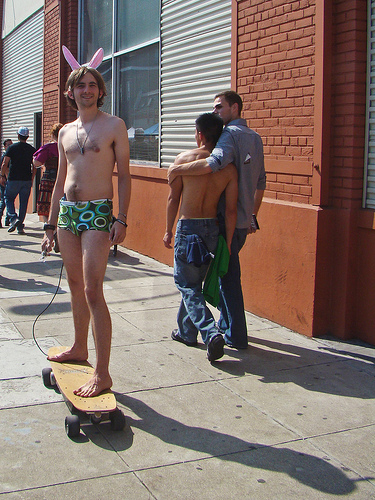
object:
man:
[40, 45, 132, 398]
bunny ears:
[62, 44, 105, 71]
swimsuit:
[57, 196, 114, 237]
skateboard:
[41, 346, 127, 439]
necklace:
[75, 109, 99, 157]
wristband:
[116, 212, 129, 226]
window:
[77, 2, 160, 168]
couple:
[163, 90, 266, 361]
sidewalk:
[0, 206, 375, 500]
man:
[162, 113, 239, 362]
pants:
[172, 218, 225, 363]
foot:
[46, 348, 113, 399]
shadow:
[111, 391, 357, 497]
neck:
[78, 101, 99, 120]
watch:
[42, 222, 56, 232]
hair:
[62, 67, 109, 112]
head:
[64, 67, 106, 109]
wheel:
[64, 414, 81, 438]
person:
[1, 125, 40, 236]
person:
[30, 122, 66, 254]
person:
[163, 113, 240, 362]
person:
[167, 92, 265, 349]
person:
[40, 69, 132, 398]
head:
[213, 91, 243, 121]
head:
[195, 113, 223, 148]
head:
[51, 123, 63, 142]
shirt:
[204, 116, 266, 230]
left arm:
[162, 152, 183, 250]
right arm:
[41, 130, 68, 257]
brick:
[37, 0, 375, 347]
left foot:
[73, 372, 113, 397]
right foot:
[45, 343, 88, 363]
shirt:
[202, 234, 229, 311]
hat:
[16, 126, 30, 137]